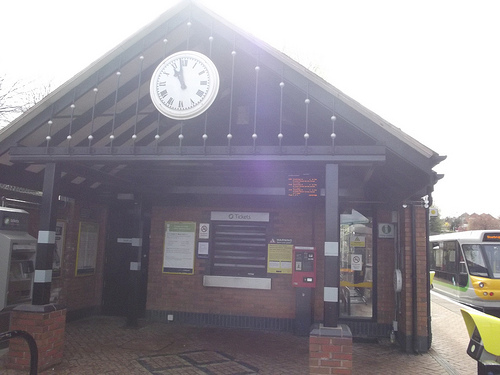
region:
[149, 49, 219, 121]
the clock is on the building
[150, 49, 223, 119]
the clock is white in color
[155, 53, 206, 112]
the clock has roman numerals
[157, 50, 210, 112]
the clock has a black inner circle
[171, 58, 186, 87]
the dial is black in color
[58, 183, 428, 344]
the building is made of brick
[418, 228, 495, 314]
a train is at the station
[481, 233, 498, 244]
a sign is on the train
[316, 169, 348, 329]
the column is made of wood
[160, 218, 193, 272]
a sign is on the wall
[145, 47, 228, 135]
clock of a rail station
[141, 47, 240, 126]
clock of a train station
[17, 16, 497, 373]
a railway station platform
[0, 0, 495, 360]
a train station platform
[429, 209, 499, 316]
the train at the station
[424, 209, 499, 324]
the train at the railway station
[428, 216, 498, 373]
the train and ticket machine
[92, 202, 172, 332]
doorway at a train station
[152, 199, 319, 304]
the counter at the train station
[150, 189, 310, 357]
the counter at the railway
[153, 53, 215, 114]
a clock on the metal bars of a building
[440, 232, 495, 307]
the head of a train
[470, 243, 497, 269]
the front window of a train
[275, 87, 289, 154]
a metal bar on the building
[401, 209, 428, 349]
a brick pillar of a building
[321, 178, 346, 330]
a black metal bar of a building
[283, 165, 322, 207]
a screen displaying some words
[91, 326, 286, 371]
a floor made of bricks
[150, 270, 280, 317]
a wall made of bricks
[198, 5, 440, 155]
the roof of a building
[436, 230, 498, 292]
a white and yellow train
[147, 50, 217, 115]
a white clock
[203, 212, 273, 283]
a window on the building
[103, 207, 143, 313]
a door on the building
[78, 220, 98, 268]
a sign on the wall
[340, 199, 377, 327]
a glass door on the building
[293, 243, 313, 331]
a red machine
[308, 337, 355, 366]
the red bricks on a post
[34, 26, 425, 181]
the roof of a building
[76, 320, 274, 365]
the floor in front of the building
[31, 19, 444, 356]
clock at a bus terminal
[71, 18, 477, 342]
the bus terminal is wood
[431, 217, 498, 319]
a bus at the station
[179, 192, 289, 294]
the sign board for times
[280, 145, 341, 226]
an updated electric sign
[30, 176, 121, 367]
poles supported by red brick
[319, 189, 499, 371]
a spot to wait inside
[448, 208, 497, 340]
the bus has yellow bumpers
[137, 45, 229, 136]
the clock numbers are black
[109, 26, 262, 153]
the numbers are roman